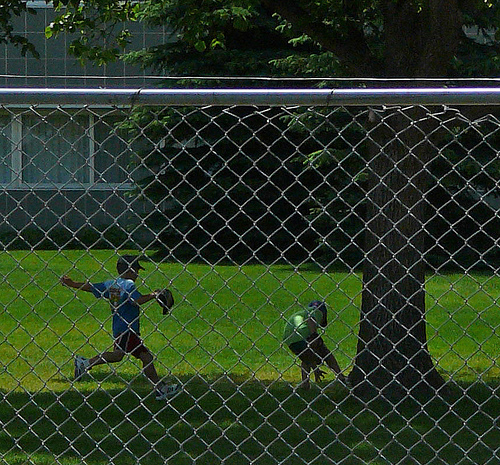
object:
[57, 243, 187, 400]
boy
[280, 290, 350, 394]
boy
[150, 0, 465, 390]
tree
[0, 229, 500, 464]
yard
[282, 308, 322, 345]
shirt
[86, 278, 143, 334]
shirt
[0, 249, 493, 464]
grass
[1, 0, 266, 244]
house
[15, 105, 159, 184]
window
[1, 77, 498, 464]
fence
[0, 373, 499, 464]
shadow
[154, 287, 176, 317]
glove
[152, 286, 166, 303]
hand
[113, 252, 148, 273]
cap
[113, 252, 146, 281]
head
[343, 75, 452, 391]
trunk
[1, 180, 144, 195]
frame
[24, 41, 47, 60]
leaves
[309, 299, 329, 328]
hat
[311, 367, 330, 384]
hand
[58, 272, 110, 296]
arm